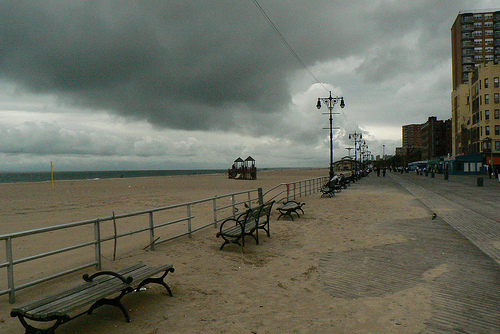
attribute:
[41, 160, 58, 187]
pole — yellow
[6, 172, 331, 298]
fence — grey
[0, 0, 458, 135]
dark clouds — thick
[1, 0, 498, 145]
clouds — black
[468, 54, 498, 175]
building — tall, brown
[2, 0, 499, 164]
sky — overcast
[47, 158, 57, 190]
pole — yellow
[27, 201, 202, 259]
fence — silver, metal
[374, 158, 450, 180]
people — walking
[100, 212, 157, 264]
gate — broken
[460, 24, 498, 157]
building — tall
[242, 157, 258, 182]
hut — small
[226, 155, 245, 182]
hut — small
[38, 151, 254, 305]
beach — sand